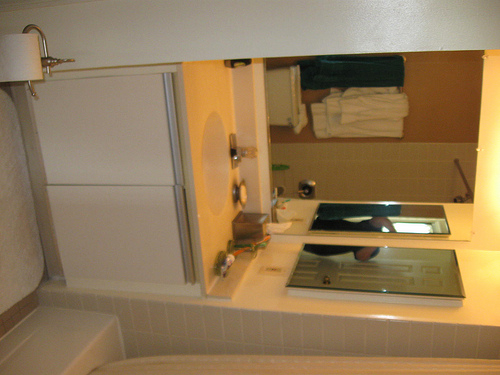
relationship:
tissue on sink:
[269, 221, 293, 235] [178, 59, 260, 302]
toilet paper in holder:
[0, 31, 46, 84] [21, 25, 62, 75]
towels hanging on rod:
[308, 58, 401, 145] [402, 57, 405, 138]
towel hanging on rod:
[295, 56, 404, 91] [402, 57, 405, 138]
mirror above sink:
[262, 52, 489, 246] [178, 59, 260, 302]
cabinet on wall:
[284, 242, 465, 307] [233, 233, 498, 327]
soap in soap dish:
[240, 185, 248, 205] [234, 179, 249, 210]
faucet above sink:
[229, 133, 255, 179] [178, 59, 260, 302]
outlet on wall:
[257, 261, 286, 281] [233, 233, 498, 327]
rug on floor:
[0, 88, 46, 317] [0, 292, 39, 340]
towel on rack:
[295, 56, 404, 91] [399, 56, 408, 138]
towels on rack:
[308, 58, 401, 145] [399, 56, 408, 138]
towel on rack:
[337, 93, 409, 123] [399, 56, 408, 138]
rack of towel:
[399, 56, 408, 138] [295, 56, 404, 91]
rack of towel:
[399, 56, 408, 138] [337, 93, 409, 123]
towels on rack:
[309, 89, 410, 146] [399, 56, 408, 138]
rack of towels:
[399, 56, 408, 138] [308, 58, 401, 145]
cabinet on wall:
[286, 238, 466, 308] [233, 233, 498, 327]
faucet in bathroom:
[229, 133, 255, 179] [3, 0, 498, 373]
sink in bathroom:
[178, 59, 260, 302] [3, 0, 498, 373]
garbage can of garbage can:
[265, 64, 308, 134] [265, 64, 308, 134]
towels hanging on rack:
[308, 58, 401, 145] [399, 56, 408, 138]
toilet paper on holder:
[0, 31, 46, 84] [21, 25, 62, 75]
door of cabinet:
[28, 71, 189, 189] [29, 66, 194, 292]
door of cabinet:
[33, 184, 198, 296] [29, 66, 194, 292]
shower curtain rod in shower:
[452, 153, 478, 205] [276, 142, 477, 203]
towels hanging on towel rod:
[308, 58, 401, 145] [399, 56, 408, 138]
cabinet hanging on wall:
[284, 242, 465, 307] [233, 233, 498, 327]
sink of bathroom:
[178, 59, 260, 302] [3, 0, 498, 373]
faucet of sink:
[229, 133, 255, 179] [178, 59, 260, 302]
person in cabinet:
[307, 241, 384, 263] [284, 242, 465, 307]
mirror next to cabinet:
[262, 52, 489, 246] [284, 242, 465, 307]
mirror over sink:
[262, 52, 489, 246] [178, 59, 260, 302]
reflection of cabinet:
[305, 195, 458, 238] [284, 242, 465, 307]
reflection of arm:
[374, 214, 397, 231] [357, 249, 373, 262]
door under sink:
[28, 71, 189, 189] [178, 59, 260, 302]